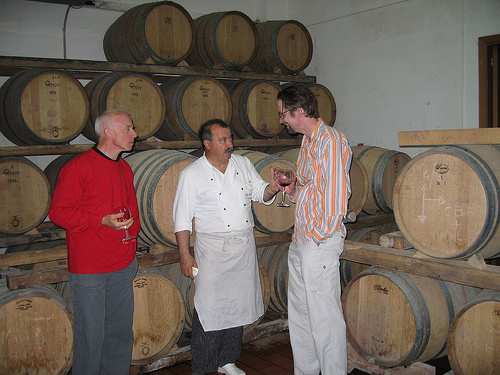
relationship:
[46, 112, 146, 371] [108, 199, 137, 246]
man holds cup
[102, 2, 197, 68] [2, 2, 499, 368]
barrel in room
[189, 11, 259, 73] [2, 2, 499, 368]
barrels in room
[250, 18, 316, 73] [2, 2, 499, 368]
barrels in room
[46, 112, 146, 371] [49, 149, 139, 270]
man wearing shirt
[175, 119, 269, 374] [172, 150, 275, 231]
man wearing shirt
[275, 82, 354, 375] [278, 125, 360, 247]
man wearing shirt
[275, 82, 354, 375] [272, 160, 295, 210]
man holding glass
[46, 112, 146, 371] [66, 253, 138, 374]
man wearing pant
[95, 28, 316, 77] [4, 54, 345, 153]
barrels stacked on shelf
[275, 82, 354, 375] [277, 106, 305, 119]
man wearing eye glasses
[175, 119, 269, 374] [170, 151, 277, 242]
man wearing shirt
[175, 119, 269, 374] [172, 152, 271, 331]
man wearing clothes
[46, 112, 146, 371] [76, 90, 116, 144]
man has hair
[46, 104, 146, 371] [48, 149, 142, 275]
man wears red shirt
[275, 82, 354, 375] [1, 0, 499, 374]
man in winery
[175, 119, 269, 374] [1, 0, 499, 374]
man in winery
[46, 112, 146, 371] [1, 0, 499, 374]
man in winery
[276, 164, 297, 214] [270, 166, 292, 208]
cup of wine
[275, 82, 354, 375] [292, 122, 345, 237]
man wearing shirt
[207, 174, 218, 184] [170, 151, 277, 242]
button on shirt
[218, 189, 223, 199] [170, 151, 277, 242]
button on shirt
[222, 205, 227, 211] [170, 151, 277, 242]
button on shirt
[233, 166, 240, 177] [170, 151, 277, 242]
button on shirt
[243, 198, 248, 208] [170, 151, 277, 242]
button on shirt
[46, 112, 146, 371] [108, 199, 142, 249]
man holding cup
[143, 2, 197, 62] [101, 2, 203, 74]
base of barrel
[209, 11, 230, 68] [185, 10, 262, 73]
strap around barrel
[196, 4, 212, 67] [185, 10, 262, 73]
strap around barrel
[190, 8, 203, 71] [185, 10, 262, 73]
strap around barrel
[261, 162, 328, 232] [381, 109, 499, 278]
glass of wine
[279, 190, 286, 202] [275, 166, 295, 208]
neck of wine glass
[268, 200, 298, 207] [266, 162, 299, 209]
base of glass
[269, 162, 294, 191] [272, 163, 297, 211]
wine in glass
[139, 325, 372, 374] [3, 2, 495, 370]
floor of cellar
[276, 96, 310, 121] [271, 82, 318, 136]
glasses on face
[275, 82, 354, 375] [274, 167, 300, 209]
man carrying glass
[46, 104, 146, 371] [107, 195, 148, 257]
man carrying glass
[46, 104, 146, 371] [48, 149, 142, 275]
man in red shirt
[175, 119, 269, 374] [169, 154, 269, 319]
man in clothes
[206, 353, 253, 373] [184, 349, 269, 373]
foot in shoes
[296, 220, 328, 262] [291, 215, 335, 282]
hand stuck in pocket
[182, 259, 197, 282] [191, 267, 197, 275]
holding object holding object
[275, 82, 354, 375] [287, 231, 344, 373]
man wearing pants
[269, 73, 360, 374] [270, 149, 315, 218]
man holding glass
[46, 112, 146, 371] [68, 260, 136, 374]
man wearing grey pants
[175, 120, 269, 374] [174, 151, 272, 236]
man wearing shirt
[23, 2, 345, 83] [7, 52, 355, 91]
barrels on a shelf